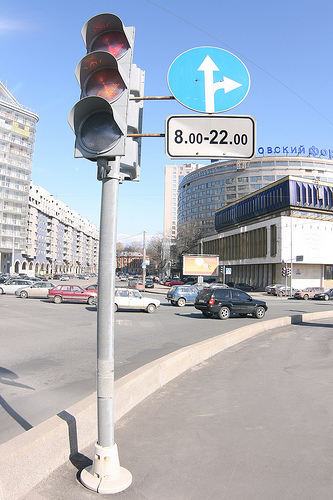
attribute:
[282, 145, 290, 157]
letter — blue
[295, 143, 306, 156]
letter — blue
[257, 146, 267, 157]
letter — blue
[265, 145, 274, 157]
letter — blue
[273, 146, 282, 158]
letter — blue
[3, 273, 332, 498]
road — grey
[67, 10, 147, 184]
traffic light — grey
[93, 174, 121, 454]
pole — grey, utility pole, tall, silver, metal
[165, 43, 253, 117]
sign board — attached, green, white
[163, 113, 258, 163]
sign board — attached, white, black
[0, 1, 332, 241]
sky — blue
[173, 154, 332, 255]
building — blue, white, huge, round, corporate, circular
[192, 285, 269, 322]
suv — parked, black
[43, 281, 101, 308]
car — red, compact, white, parked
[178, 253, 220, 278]
billboard — orange, short, advertising, orange black, white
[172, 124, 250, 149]
times — specific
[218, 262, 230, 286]
street light — right of picture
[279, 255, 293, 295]
street light — right of picture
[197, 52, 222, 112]
arrow — white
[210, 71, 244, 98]
arrow — white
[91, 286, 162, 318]
car — parked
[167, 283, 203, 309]
car — parked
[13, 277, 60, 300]
car — parked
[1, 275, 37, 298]
car — parked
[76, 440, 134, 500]
base — flat, wide, white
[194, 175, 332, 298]
building — square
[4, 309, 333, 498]
curve — white, concrete, gray